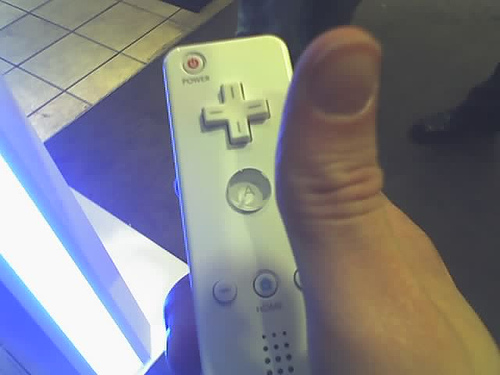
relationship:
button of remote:
[226, 168, 271, 213] [162, 32, 311, 372]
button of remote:
[210, 274, 239, 306] [162, 32, 311, 372]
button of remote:
[251, 266, 277, 299] [162, 32, 311, 372]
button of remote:
[181, 52, 207, 74] [162, 32, 311, 372]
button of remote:
[199, 79, 265, 150] [162, 32, 311, 372]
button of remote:
[202, 82, 269, 145] [162, 32, 311, 372]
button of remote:
[213, 278, 238, 303] [162, 32, 311, 372]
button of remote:
[254, 272, 278, 297] [162, 32, 311, 372]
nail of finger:
[306, 46, 379, 116] [273, 25, 419, 292]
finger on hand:
[273, 25, 419, 292] [156, 25, 494, 372]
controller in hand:
[151, 31, 320, 373] [270, 22, 497, 372]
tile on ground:
[1, 0, 234, 144] [8, 1, 494, 334]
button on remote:
[178, 48, 208, 75] [162, 32, 311, 372]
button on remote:
[202, 82, 269, 145] [162, 32, 311, 372]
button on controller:
[226, 168, 271, 213] [161, 33, 312, 375]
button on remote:
[181, 257, 315, 317] [162, 32, 311, 372]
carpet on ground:
[43, 6, 237, 266] [0, 0, 497, 373]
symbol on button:
[187, 57, 199, 67] [178, 46, 203, 72]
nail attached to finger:
[306, 46, 379, 116] [273, 25, 419, 292]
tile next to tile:
[1, 11, 151, 129] [76, 3, 161, 52]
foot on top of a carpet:
[407, 112, 485, 146] [43, 0, 355, 266]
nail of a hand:
[302, 40, 379, 117] [156, 25, 494, 372]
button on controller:
[226, 168, 271, 213] [237, 90, 292, 213]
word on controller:
[178, 74, 212, 83] [151, 31, 320, 373]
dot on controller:
[261, 330, 269, 342] [151, 31, 320, 373]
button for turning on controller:
[181, 52, 207, 74] [151, 31, 320, 373]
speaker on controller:
[256, 318, 301, 373] [151, 31, 320, 373]